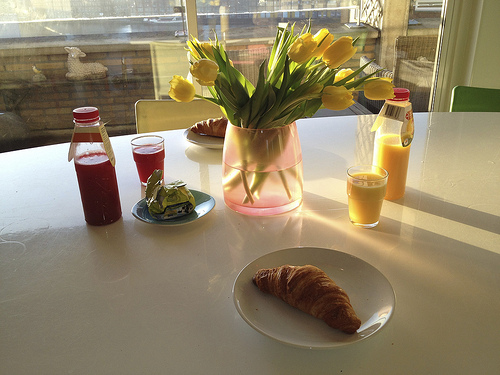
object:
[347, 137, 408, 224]
orange juice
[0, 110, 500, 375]
ground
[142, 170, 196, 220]
wrapper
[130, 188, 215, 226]
plate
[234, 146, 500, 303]
shadows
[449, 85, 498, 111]
chair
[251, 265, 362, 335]
croissant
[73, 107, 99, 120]
red cap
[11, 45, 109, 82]
wall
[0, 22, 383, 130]
brick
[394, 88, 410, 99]
cap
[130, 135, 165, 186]
glass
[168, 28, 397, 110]
flowers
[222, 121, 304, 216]
vase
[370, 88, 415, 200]
bottle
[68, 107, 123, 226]
bottle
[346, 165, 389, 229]
glass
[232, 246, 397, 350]
dish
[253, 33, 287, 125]
stem